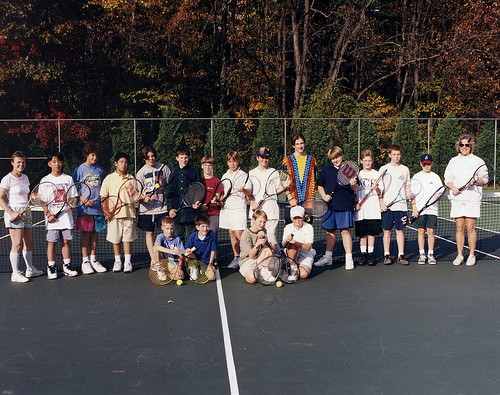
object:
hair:
[456, 134, 477, 153]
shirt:
[444, 152, 488, 202]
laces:
[48, 265, 56, 273]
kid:
[0, 150, 43, 283]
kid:
[137, 145, 171, 265]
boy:
[244, 147, 293, 254]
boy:
[281, 205, 316, 282]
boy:
[100, 155, 141, 272]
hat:
[420, 154, 433, 165]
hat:
[290, 205, 306, 218]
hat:
[257, 147, 272, 157]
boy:
[153, 216, 186, 281]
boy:
[185, 216, 216, 281]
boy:
[315, 146, 360, 270]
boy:
[165, 146, 202, 245]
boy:
[193, 155, 224, 270]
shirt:
[316, 163, 360, 212]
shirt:
[165, 167, 202, 224]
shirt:
[194, 176, 226, 214]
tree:
[8, 100, 84, 138]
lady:
[443, 136, 489, 267]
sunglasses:
[459, 143, 470, 147]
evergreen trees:
[149, 107, 185, 164]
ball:
[275, 281, 282, 288]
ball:
[176, 279, 184, 286]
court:
[4, 197, 499, 391]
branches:
[432, 3, 500, 63]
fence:
[1, 114, 496, 204]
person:
[377, 144, 412, 265]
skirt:
[450, 201, 480, 218]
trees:
[423, 3, 499, 156]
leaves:
[447, 50, 492, 92]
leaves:
[159, 4, 204, 40]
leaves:
[7, 49, 51, 81]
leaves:
[471, 7, 493, 30]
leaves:
[124, 86, 175, 107]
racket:
[410, 185, 448, 223]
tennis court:
[0, 191, 498, 392]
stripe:
[215, 263, 240, 393]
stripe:
[403, 225, 498, 262]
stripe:
[438, 215, 499, 234]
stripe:
[0, 216, 47, 242]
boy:
[410, 154, 443, 265]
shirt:
[411, 169, 444, 217]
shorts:
[76, 215, 106, 233]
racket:
[206, 177, 233, 206]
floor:
[0, 264, 498, 391]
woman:
[282, 134, 317, 253]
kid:
[38, 153, 79, 281]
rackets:
[174, 181, 206, 213]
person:
[354, 148, 384, 266]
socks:
[9, 252, 21, 273]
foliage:
[8, 105, 91, 153]